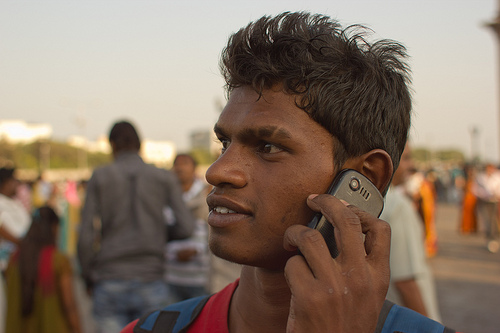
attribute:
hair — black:
[214, 7, 414, 181]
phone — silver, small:
[299, 155, 397, 264]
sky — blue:
[53, 8, 165, 75]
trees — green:
[0, 136, 111, 168]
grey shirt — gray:
[74, 160, 199, 284]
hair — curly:
[217, 5, 341, 82]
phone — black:
[315, 163, 395, 249]